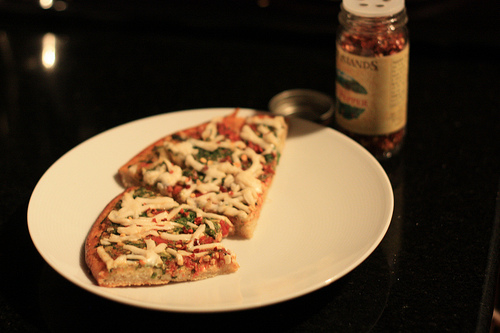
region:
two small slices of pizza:
[70, 81, 305, 296]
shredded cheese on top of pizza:
[90, 170, 230, 285]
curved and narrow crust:
[75, 182, 130, 288]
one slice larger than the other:
[71, 107, 291, 287]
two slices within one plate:
[26, 92, 406, 309]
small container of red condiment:
[317, 0, 413, 165]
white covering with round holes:
[342, 0, 402, 17]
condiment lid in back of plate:
[266, 80, 336, 125]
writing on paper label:
[335, 42, 405, 137]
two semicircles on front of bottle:
[330, 65, 386, 130]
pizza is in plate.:
[85, 130, 283, 291]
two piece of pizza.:
[80, 155, 305, 301]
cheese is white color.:
[116, 161, 236, 272]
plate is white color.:
[283, 200, 356, 283]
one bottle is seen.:
[343, 22, 428, 98]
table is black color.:
[400, 155, 496, 310]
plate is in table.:
[310, 208, 413, 329]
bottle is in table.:
[338, 97, 441, 198]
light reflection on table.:
[17, 0, 82, 80]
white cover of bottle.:
[342, 1, 422, 26]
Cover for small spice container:
[267, 85, 334, 132]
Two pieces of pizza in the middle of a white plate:
[75, 119, 354, 301]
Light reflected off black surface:
[19, 1, 79, 73]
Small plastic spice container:
[327, 0, 424, 152]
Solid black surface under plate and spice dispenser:
[411, 155, 489, 316]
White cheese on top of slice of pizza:
[208, 166, 259, 217]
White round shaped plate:
[20, 82, 405, 314]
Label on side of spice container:
[330, 60, 385, 130]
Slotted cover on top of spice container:
[338, 1, 413, 22]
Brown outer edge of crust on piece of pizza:
[80, 205, 106, 280]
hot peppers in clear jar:
[335, 0, 437, 155]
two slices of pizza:
[91, 106, 298, 296]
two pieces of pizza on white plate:
[32, 96, 369, 317]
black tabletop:
[381, 124, 496, 319]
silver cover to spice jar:
[262, 85, 336, 135]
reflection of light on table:
[12, 0, 90, 84]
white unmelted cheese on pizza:
[117, 193, 167, 240]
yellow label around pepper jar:
[322, 38, 427, 127]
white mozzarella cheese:
[117, 206, 160, 244]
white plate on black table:
[27, 64, 404, 317]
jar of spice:
[329, 0, 419, 162]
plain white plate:
[19, 106, 394, 314]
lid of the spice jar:
[264, 81, 334, 126]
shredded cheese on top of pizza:
[116, 190, 168, 237]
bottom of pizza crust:
[95, 266, 170, 283]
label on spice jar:
[331, 53, 406, 128]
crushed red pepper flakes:
[346, 35, 401, 51]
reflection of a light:
[31, 33, 58, 70]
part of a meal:
[62, 110, 297, 288]